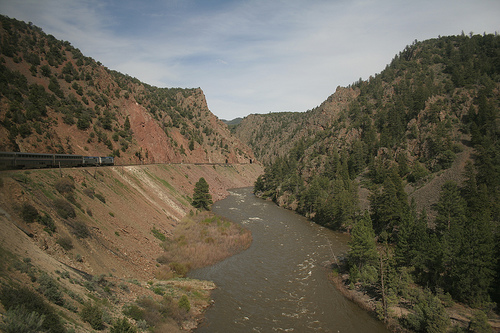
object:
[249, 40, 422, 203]
slope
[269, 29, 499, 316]
forest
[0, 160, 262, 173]
railway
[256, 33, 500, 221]
hill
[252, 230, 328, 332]
water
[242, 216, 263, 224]
waves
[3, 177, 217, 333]
bank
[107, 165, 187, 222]
white spot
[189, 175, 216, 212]
shrubbery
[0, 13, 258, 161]
mountain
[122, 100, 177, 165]
clear spot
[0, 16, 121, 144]
trees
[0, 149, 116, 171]
train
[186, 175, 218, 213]
tree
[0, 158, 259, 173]
tracks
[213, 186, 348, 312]
river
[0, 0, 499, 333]
canyon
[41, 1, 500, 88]
sky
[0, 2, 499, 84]
clouds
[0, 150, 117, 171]
railroad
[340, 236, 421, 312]
shrubs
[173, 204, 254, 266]
bank